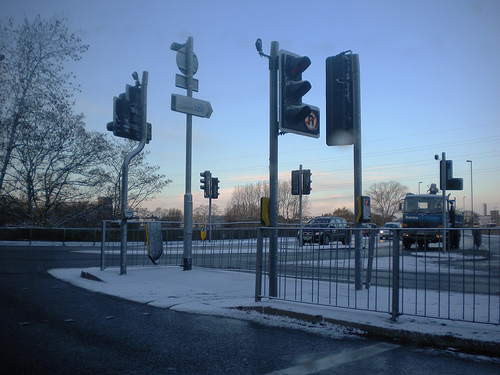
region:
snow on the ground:
[153, 257, 422, 336]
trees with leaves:
[6, 1, 98, 207]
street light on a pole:
[265, 51, 335, 165]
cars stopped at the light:
[284, 183, 474, 262]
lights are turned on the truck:
[386, 231, 472, 248]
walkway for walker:
[115, 235, 494, 327]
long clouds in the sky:
[124, 149, 421, 214]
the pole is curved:
[112, 61, 159, 258]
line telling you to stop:
[243, 314, 466, 371]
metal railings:
[285, 234, 498, 356]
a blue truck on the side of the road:
[402, 193, 461, 245]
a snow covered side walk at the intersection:
[119, 268, 256, 312]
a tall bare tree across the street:
[4, 17, 101, 217]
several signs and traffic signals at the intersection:
[97, 29, 390, 179]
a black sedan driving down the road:
[291, 213, 356, 243]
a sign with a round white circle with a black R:
[302, 105, 319, 134]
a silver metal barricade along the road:
[276, 226, 498, 326]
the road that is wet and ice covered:
[1, 243, 83, 370]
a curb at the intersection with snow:
[251, 301, 388, 348]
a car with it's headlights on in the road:
[378, 216, 403, 243]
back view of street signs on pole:
[164, 28, 224, 281]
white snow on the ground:
[120, 267, 238, 299]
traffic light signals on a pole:
[252, 32, 312, 305]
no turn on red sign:
[300, 101, 315, 145]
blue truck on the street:
[384, 182, 473, 255]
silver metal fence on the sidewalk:
[246, 223, 498, 332]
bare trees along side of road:
[7, 12, 97, 227]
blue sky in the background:
[86, 4, 495, 38]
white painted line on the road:
[252, 339, 412, 374]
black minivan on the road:
[294, 212, 356, 249]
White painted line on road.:
[307, 325, 395, 373]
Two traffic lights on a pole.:
[283, 163, 317, 271]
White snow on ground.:
[146, 272, 246, 309]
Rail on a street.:
[0, 212, 100, 253]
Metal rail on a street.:
[196, 217, 494, 342]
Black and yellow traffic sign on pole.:
[241, 187, 280, 235]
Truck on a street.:
[376, 179, 473, 263]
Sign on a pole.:
[343, 185, 398, 253]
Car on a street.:
[283, 207, 368, 274]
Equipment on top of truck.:
[406, 172, 440, 204]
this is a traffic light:
[276, 48, 319, 146]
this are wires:
[390, 135, 430, 180]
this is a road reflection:
[256, 187, 275, 240]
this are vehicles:
[286, 207, 399, 245]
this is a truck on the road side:
[394, 190, 477, 249]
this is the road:
[22, 305, 205, 364]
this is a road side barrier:
[245, 221, 493, 329]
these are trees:
[0, 67, 112, 223]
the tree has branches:
[0, 65, 110, 221]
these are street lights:
[461, 157, 497, 220]